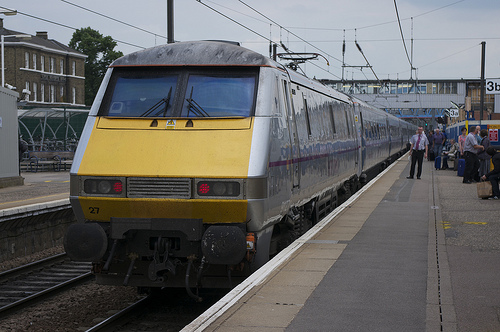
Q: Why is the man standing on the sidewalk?
A: Waiting to board the train.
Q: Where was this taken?
A: Train station.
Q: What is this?
A: Train.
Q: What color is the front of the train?
A: Yellow.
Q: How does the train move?
A: Along tracks.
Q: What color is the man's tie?
A: Red.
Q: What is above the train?
A: Power lines.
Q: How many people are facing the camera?
A: One.